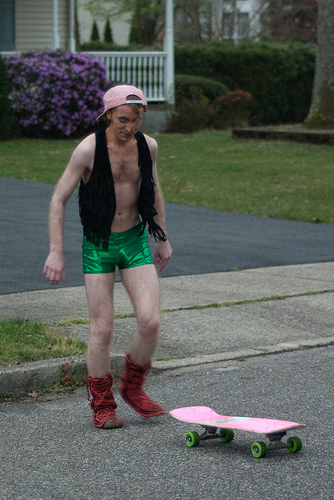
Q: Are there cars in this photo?
A: No, there are no cars.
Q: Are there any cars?
A: No, there are no cars.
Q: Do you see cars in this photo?
A: No, there are no cars.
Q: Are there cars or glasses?
A: No, there are no cars or glasses.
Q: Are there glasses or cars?
A: No, there are no cars or glasses.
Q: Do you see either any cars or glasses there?
A: No, there are no cars or glasses.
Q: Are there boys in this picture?
A: No, there are no boys.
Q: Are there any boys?
A: No, there are no boys.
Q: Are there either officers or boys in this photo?
A: No, there are no boys or officers.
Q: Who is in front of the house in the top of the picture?
A: The man is in front of the house.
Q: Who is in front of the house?
A: The man is in front of the house.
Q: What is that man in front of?
A: The man is in front of the house.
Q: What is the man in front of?
A: The man is in front of the house.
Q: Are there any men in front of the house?
A: Yes, there is a man in front of the house.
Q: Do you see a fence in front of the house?
A: No, there is a man in front of the house.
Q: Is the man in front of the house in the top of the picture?
A: Yes, the man is in front of the house.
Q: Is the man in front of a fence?
A: No, the man is in front of the house.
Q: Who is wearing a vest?
A: The man is wearing a vest.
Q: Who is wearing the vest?
A: The man is wearing a vest.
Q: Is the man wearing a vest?
A: Yes, the man is wearing a vest.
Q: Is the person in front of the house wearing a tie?
A: No, the man is wearing a vest.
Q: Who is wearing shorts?
A: The man is wearing shorts.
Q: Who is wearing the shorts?
A: The man is wearing shorts.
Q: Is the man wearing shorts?
A: Yes, the man is wearing shorts.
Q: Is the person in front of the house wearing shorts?
A: Yes, the man is wearing shorts.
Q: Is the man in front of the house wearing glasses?
A: No, the man is wearing shorts.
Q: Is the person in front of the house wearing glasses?
A: No, the man is wearing shorts.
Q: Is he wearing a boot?
A: Yes, the man is wearing a boot.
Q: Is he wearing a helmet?
A: No, the man is wearing a boot.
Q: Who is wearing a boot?
A: The man is wearing a boot.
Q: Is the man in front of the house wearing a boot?
A: Yes, the man is wearing a boot.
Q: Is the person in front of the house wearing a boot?
A: Yes, the man is wearing a boot.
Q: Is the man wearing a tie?
A: No, the man is wearing a boot.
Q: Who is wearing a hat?
A: The man is wearing a hat.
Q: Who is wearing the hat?
A: The man is wearing a hat.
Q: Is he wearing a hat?
A: Yes, the man is wearing a hat.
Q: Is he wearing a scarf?
A: No, the man is wearing a hat.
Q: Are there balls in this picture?
A: No, there are no balls.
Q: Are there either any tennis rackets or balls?
A: No, there are no balls or tennis rackets.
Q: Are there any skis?
A: No, there are no skis.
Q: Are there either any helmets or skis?
A: No, there are no skis or helmets.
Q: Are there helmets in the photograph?
A: No, there are no helmets.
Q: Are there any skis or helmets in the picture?
A: No, there are no helmets or skis.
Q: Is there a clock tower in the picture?
A: No, there are no clock towers.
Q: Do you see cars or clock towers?
A: No, there are no clock towers or cars.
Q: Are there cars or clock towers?
A: No, there are no clock towers or cars.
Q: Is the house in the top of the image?
A: Yes, the house is in the top of the image.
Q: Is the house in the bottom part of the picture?
A: No, the house is in the top of the image.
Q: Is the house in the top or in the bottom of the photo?
A: The house is in the top of the image.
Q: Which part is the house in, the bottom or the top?
A: The house is in the top of the image.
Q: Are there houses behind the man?
A: Yes, there is a house behind the man.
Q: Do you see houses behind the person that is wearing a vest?
A: Yes, there is a house behind the man.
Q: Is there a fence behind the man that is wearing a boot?
A: No, there is a house behind the man.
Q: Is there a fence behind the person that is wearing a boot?
A: No, there is a house behind the man.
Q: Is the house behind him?
A: Yes, the house is behind a man.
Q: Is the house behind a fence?
A: No, the house is behind a man.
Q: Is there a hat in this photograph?
A: Yes, there is a hat.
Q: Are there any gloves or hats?
A: Yes, there is a hat.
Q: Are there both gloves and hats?
A: No, there is a hat but no gloves.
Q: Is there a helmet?
A: No, there are no helmets.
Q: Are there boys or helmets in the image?
A: No, there are no helmets or boys.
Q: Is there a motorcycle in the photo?
A: No, there are no motorcycles.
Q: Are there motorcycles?
A: No, there are no motorcycles.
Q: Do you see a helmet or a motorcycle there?
A: No, there are no motorcycles or helmets.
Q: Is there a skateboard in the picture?
A: Yes, there is a skateboard.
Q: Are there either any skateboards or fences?
A: Yes, there is a skateboard.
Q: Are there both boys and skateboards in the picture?
A: No, there is a skateboard but no boys.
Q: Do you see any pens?
A: No, there are no pens.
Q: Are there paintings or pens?
A: No, there are no pens or paintings.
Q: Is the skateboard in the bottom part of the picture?
A: Yes, the skateboard is in the bottom of the image.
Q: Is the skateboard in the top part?
A: No, the skateboard is in the bottom of the image.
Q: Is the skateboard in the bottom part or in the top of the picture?
A: The skateboard is in the bottom of the image.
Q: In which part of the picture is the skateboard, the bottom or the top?
A: The skateboard is in the bottom of the image.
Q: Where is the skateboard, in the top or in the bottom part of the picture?
A: The skateboard is in the bottom of the image.